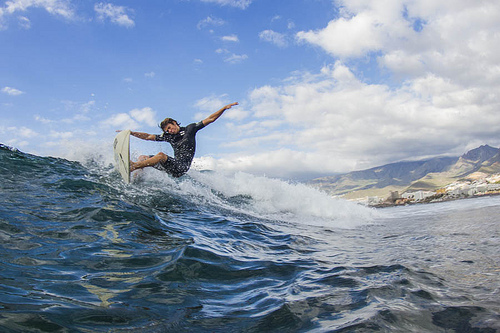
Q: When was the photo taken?
A: Afternoon.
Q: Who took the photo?
A: Photographer.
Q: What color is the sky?
A: Blue.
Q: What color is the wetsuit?
A: Black.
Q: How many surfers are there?
A: 1.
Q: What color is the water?
A: Navy.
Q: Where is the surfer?
A: Ocean.